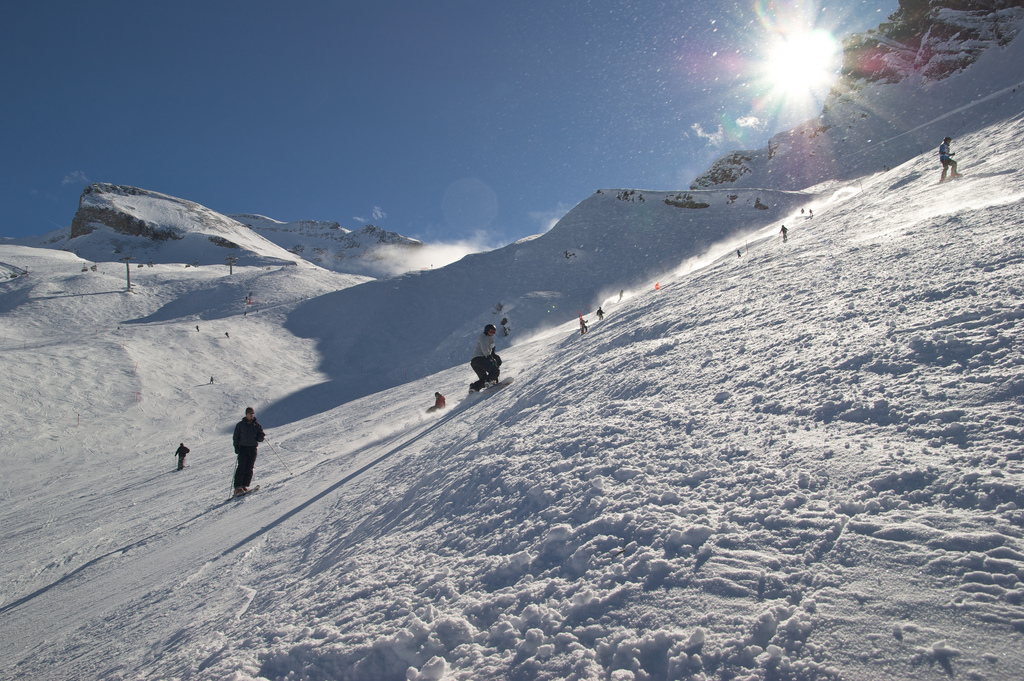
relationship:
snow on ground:
[230, 552, 349, 633] [249, 217, 1001, 675]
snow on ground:
[846, 321, 968, 402] [249, 217, 1001, 675]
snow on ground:
[555, 417, 654, 482] [249, 217, 1001, 675]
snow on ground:
[694, 422, 840, 563] [249, 217, 1001, 675]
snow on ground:
[553, 518, 627, 621] [249, 217, 1001, 675]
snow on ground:
[855, 578, 957, 624] [342, 268, 889, 636]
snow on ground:
[822, 483, 881, 556] [342, 268, 889, 636]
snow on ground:
[717, 543, 757, 592] [342, 268, 889, 636]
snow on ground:
[755, 555, 857, 601] [342, 268, 889, 636]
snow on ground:
[755, 547, 785, 601] [342, 268, 889, 636]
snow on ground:
[998, 584, 1014, 660] [418, 437, 855, 630]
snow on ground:
[812, 624, 870, 644] [418, 437, 855, 630]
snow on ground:
[872, 594, 930, 629] [418, 437, 855, 630]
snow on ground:
[960, 562, 986, 611] [418, 437, 855, 630]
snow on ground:
[919, 643, 951, 663] [418, 437, 855, 630]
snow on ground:
[860, 322, 1001, 358] [521, 458, 803, 662]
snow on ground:
[806, 471, 924, 528] [521, 458, 803, 662]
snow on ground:
[893, 425, 955, 505] [521, 458, 803, 662]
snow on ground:
[789, 376, 882, 449] [521, 458, 803, 662]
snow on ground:
[954, 395, 1009, 472] [521, 458, 803, 662]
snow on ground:
[695, 455, 803, 538] [467, 428, 956, 677]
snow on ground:
[587, 549, 696, 644] [467, 428, 956, 677]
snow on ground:
[929, 552, 1009, 650] [467, 428, 956, 677]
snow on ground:
[790, 533, 901, 629] [467, 428, 956, 677]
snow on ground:
[702, 571, 802, 660] [467, 428, 956, 677]